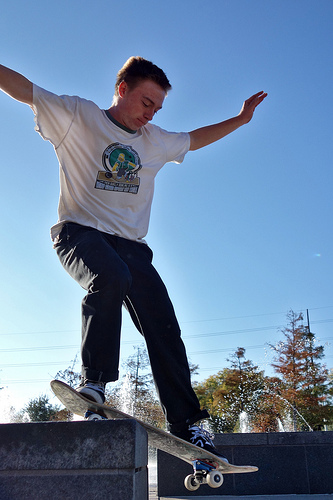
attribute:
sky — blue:
[1, 29, 332, 401]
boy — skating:
[3, 49, 272, 462]